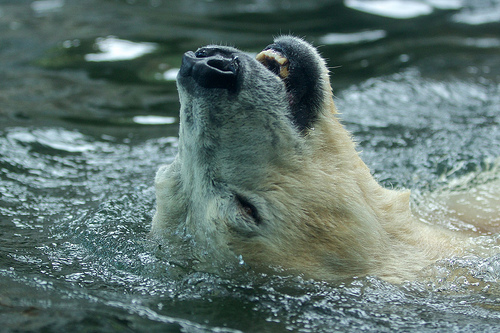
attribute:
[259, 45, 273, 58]
tooth — yellow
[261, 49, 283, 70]
tooth — yellow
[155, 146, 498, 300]
fur — white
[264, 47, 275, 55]
tooth — yellow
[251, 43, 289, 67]
teeth — white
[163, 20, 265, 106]
nostril — black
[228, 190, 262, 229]
eye — closed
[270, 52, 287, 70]
tooth — yellow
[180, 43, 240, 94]
nose — black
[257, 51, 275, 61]
tooth — yellow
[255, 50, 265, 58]
tooth — yellow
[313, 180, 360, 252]
fur — white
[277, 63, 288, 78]
tooth — yellow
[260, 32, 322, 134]
lips — black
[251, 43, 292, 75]
teeth — yellow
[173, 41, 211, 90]
nose — black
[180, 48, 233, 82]
nostril — black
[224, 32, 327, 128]
mouth — open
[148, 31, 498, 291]
bear — polar